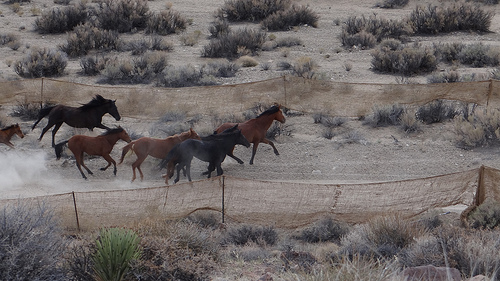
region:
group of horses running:
[10, 78, 310, 202]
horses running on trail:
[0, 73, 315, 191]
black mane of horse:
[258, 103, 275, 117]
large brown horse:
[254, 93, 299, 160]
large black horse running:
[179, 130, 256, 170]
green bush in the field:
[89, 225, 138, 260]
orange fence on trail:
[224, 173, 474, 218]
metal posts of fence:
[218, 178, 230, 223]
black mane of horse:
[85, 92, 106, 109]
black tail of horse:
[48, 138, 75, 156]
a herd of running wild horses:
[1, 97, 290, 177]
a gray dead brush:
[2, 191, 59, 277]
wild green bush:
[97, 228, 137, 279]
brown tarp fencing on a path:
[0, 171, 497, 223]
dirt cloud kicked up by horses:
[1, 141, 50, 191]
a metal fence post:
[221, 174, 226, 226]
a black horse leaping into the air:
[33, 94, 121, 141]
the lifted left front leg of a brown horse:
[263, 138, 281, 156]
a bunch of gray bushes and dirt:
[1, 1, 498, 91]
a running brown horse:
[50, 127, 131, 177]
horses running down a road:
[8, 101, 298, 186]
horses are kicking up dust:
[0, 101, 280, 176]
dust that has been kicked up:
[0, 145, 56, 188]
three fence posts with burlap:
[5, 185, 495, 233]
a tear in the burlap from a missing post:
[325, 170, 345, 225]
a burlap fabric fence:
[2, 72, 493, 112]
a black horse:
[166, 130, 252, 176]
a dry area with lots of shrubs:
[0, 5, 490, 277]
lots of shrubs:
[17, 7, 487, 77]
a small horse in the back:
[2, 122, 24, 157]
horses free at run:
[25, 91, 377, 99]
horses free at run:
[38, 61, 290, 278]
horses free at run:
[5, 53, 337, 195]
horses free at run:
[8, 71, 376, 137]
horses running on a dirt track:
[3, 86, 293, 193]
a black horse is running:
[36, 90, 123, 151]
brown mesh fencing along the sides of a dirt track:
[1, 60, 498, 242]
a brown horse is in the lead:
[211, 101, 290, 168]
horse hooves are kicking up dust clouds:
[1, 113, 237, 188]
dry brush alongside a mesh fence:
[154, 211, 499, 279]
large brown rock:
[400, 255, 470, 279]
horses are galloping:
[3, 89, 290, 186]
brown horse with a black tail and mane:
[52, 124, 139, 179]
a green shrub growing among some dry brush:
[73, 218, 178, 280]